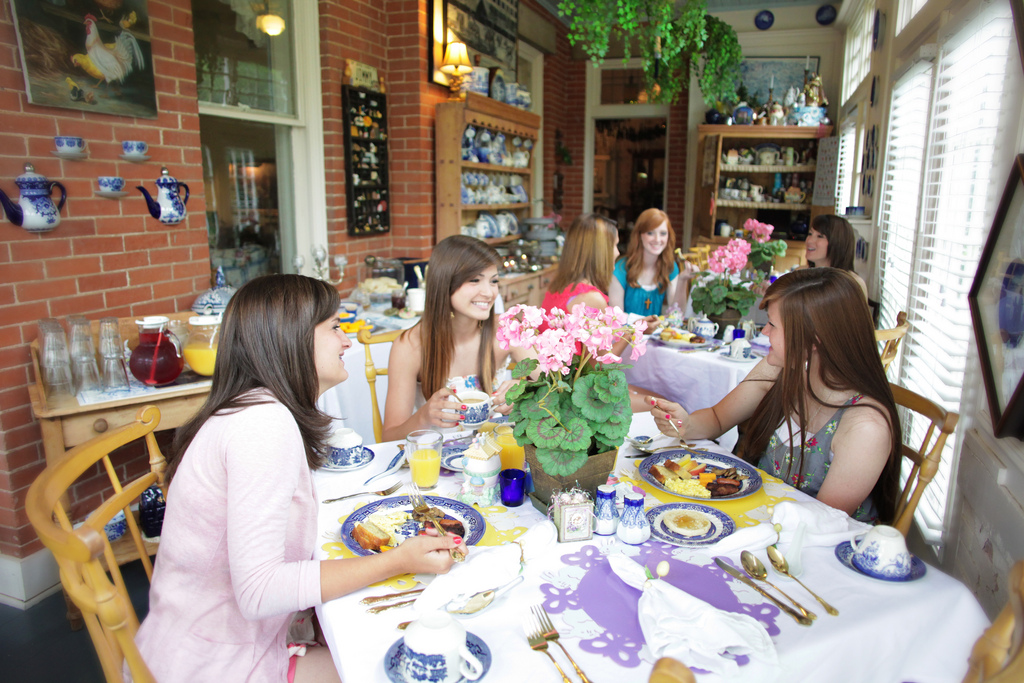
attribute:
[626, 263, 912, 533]
person — sitting down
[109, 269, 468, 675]
girl — teenage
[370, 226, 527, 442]
girl — teenage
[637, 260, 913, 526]
girl — teenage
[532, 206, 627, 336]
girl — teenage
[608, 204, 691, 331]
girl — teenage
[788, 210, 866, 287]
girl — teenage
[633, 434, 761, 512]
plate — white, blue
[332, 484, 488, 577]
plate — blue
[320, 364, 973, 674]
table — white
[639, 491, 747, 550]
plate — white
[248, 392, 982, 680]
table — blue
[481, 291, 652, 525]
plant — green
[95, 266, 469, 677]
person — sitting down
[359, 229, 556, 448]
person — sitting down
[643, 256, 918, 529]
person — sitting down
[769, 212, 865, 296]
person — sitting down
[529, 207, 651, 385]
person — sitting down